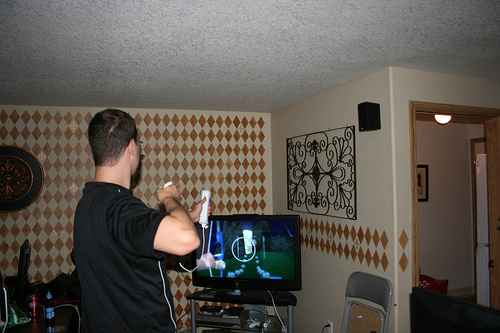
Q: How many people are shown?
A: One.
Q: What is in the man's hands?
A: WII controllers.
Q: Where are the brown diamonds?
A: Wall.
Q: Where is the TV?
A: In front of the man.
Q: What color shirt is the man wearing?
A: Black.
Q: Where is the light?
A: Other room.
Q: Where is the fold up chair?
A: Beside the door.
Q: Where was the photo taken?
A: In the living room.